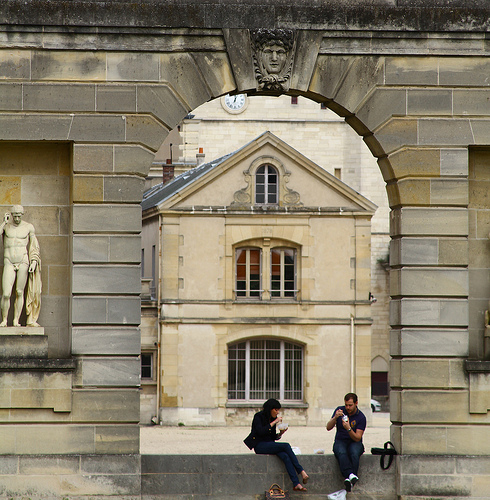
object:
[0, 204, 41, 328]
statue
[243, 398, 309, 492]
person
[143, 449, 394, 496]
step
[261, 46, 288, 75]
face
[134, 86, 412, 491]
archway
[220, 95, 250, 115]
clock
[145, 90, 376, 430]
front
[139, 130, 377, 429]
building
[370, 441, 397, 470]
bag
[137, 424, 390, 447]
ground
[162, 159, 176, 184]
chimney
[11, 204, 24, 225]
head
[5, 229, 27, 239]
chest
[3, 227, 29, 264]
torso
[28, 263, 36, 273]
left hand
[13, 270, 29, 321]
left leg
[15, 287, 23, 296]
left knee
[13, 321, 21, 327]
left foot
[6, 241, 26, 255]
abs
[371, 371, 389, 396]
door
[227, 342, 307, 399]
window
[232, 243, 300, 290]
window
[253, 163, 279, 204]
window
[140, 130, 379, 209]
arch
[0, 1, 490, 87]
top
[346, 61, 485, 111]
bricks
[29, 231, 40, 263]
arm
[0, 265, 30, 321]
legs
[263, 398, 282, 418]
woman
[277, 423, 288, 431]
ice cream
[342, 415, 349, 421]
ice cream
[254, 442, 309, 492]
cross legged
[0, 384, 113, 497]
wall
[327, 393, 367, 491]
man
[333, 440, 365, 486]
cross legged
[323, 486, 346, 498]
bag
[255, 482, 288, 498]
handbag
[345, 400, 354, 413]
face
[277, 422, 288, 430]
container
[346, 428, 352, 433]
watch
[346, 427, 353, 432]
wrist